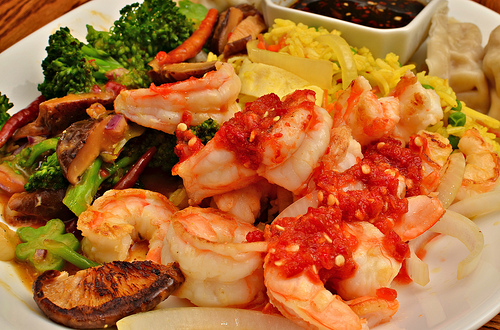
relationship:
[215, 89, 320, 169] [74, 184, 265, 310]
marinara sauce slathered shrimp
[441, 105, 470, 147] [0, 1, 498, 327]
pea on plate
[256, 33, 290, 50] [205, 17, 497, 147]
carrot in rice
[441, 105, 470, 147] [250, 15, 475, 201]
pea in fried rice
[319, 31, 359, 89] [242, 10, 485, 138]
onion in fried rice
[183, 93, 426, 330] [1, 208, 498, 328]
shrimp on plate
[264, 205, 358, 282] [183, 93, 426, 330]
sauce on top of shrimp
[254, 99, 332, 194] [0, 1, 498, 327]
shrimp on plate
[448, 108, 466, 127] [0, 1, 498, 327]
pea on top of plate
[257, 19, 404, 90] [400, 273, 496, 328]
rice on top of plate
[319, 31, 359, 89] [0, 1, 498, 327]
onion on top of plate